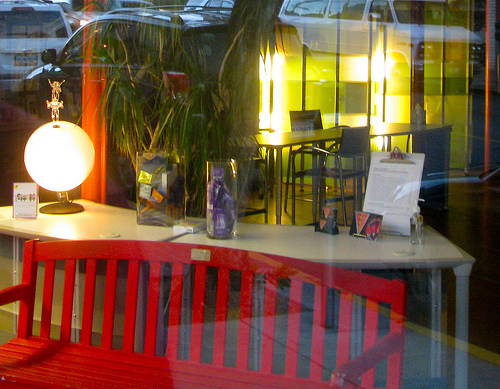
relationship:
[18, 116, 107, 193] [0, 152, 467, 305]
lamp on counter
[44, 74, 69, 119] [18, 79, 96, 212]
object on lamp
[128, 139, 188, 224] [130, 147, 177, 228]
vase filled with object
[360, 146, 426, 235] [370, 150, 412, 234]
clip board filled with paper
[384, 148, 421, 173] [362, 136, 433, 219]
silver clip on top of board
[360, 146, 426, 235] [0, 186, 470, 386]
clip board on table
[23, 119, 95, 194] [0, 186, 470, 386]
lamp on table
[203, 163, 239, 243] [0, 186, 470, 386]
jar on table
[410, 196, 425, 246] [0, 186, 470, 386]
sanitizer on table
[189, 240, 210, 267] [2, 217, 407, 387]
sign on bench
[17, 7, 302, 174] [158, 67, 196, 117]
reflection of tail light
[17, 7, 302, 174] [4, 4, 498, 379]
reflection in window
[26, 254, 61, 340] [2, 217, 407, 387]
slat of bench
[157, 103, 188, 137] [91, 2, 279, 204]
leaves on plant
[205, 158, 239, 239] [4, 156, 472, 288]
jar on table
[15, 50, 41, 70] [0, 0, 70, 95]
license plate on a car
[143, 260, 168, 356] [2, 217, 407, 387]
slat on a bench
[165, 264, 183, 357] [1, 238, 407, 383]
slat on a bench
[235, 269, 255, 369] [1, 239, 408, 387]
slat on a red bench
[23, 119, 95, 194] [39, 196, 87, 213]
lamp on a stand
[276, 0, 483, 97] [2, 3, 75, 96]
reflection of a van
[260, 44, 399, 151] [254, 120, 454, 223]
light behind a desk